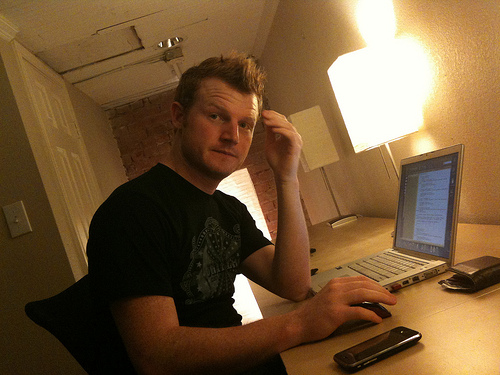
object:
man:
[85, 50, 398, 374]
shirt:
[85, 163, 274, 327]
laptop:
[307, 143, 464, 297]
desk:
[244, 213, 500, 375]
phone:
[333, 326, 423, 372]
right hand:
[300, 274, 398, 343]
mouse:
[328, 303, 393, 337]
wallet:
[438, 255, 500, 294]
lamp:
[326, 44, 419, 182]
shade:
[325, 45, 419, 153]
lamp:
[286, 105, 359, 230]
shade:
[284, 104, 340, 172]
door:
[0, 40, 105, 282]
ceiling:
[0, 1, 279, 112]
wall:
[108, 87, 314, 243]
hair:
[173, 50, 267, 109]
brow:
[208, 102, 229, 113]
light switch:
[1, 200, 34, 239]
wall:
[1, 59, 89, 373]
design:
[180, 217, 242, 305]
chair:
[24, 273, 131, 375]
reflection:
[354, 0, 441, 157]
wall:
[261, 3, 500, 225]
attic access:
[71, 58, 182, 111]